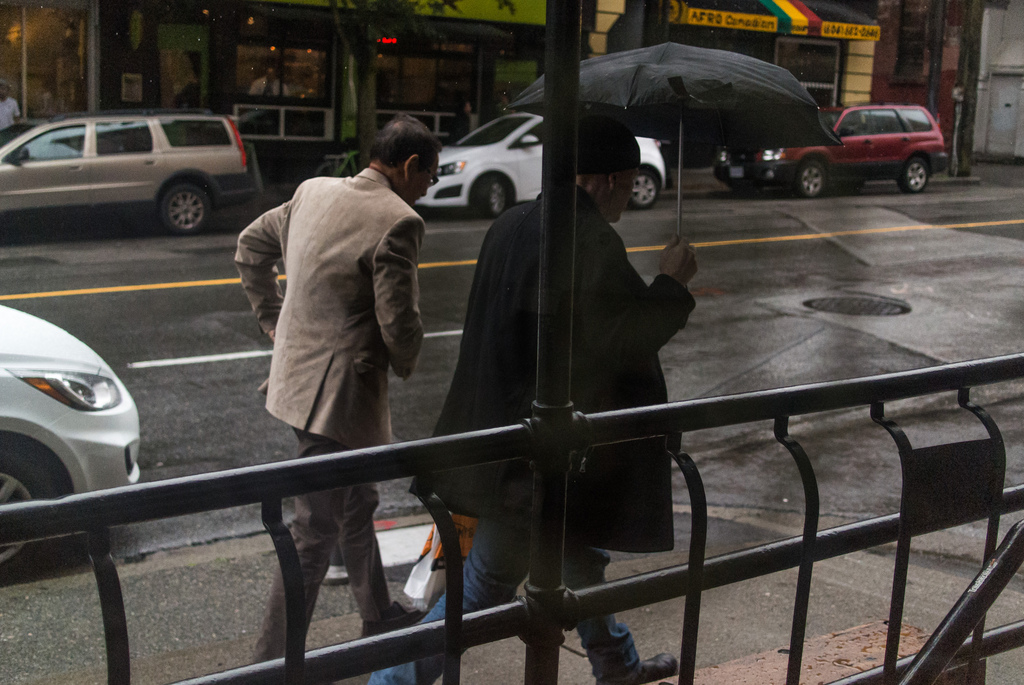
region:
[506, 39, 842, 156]
An opened black umbrella.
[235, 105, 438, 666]
Dark haired man walking in a brown coat.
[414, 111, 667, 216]
A white parked car in front of a red suv.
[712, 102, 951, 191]
A red suv parked.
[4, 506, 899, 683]
A black paved sidewalk two men are walking on.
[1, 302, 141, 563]
Front of a white car behind two men.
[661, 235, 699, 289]
A mans right hand holding an umbrella pole.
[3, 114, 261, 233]
A light gold colored suv.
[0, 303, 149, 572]
Car is parked on the street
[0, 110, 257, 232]
Car is parked on the street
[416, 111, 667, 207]
Car is parked on the street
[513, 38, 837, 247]
Man is holding an umbrella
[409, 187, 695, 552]
Man is wearing a black jacket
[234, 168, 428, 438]
Man is wearing a brown jacket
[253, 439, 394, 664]
Man is wearing brown pants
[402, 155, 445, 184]
Man is wearing glasses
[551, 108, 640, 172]
Man is wearing a hat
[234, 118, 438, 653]
person on the sidewalk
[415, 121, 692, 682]
person on the sidewalk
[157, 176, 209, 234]
wheel on a vehicle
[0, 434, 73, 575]
wheel on a vehicle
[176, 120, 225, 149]
a window on the vehicle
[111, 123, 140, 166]
a window on the vehicle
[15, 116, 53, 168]
a window on the vehicle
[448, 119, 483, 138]
a window on the vehicle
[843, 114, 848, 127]
a window on the vehicle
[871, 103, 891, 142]
a window on the vehicle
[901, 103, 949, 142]
a window on the vehicle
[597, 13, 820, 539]
a person walking on the sidewalk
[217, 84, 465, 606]
a person walking on the sidewalk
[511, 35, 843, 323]
the man is holding an umbrella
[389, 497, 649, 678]
the man is wearing jeans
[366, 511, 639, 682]
the jeans are blue in color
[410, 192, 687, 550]
the man is wearing a coat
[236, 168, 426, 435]
the man is wearing a blazer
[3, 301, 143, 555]
the car is white in color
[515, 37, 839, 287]
the umbrella is black in color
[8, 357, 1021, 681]
a railing is made of metal